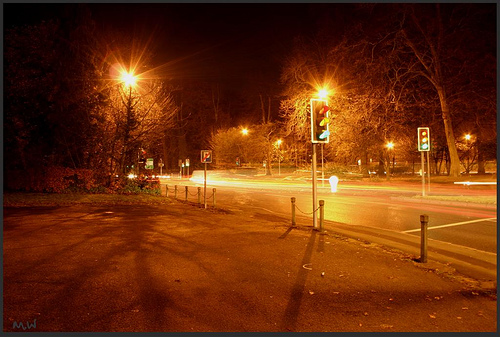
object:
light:
[316, 88, 332, 101]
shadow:
[277, 226, 321, 334]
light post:
[309, 95, 332, 231]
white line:
[400, 214, 499, 234]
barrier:
[418, 212, 430, 263]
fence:
[160, 182, 217, 211]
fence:
[287, 195, 327, 230]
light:
[329, 173, 340, 193]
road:
[135, 168, 498, 255]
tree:
[382, 12, 472, 177]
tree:
[87, 32, 195, 193]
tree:
[273, 19, 430, 178]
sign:
[201, 148, 212, 210]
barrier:
[317, 199, 325, 231]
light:
[115, 70, 142, 88]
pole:
[309, 141, 321, 228]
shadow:
[6, 198, 261, 330]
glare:
[308, 192, 378, 224]